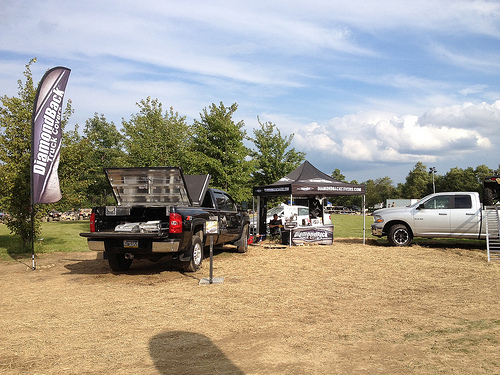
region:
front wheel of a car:
[393, 230, 403, 240]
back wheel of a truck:
[193, 239, 198, 254]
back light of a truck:
[168, 217, 182, 229]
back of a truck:
[131, 192, 160, 233]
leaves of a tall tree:
[214, 119, 231, 126]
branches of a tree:
[122, 117, 151, 138]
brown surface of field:
[316, 262, 344, 354]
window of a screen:
[430, 195, 465, 200]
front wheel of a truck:
[236, 232, 249, 244]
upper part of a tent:
[301, 177, 324, 184]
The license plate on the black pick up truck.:
[117, 239, 139, 251]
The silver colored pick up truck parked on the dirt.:
[365, 173, 499, 247]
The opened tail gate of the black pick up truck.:
[77, 227, 178, 241]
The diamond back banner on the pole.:
[32, 60, 74, 213]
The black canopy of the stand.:
[253, 152, 368, 198]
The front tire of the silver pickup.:
[386, 226, 410, 242]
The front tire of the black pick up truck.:
[239, 224, 254, 252]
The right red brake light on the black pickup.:
[165, 212, 182, 236]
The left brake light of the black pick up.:
[85, 209, 97, 231]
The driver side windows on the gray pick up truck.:
[415, 199, 472, 209]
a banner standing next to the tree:
[26, 66, 72, 263]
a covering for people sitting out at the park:
[256, 157, 366, 244]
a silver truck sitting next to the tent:
[372, 189, 497, 239]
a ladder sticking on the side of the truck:
[478, 202, 499, 271]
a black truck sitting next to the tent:
[88, 167, 252, 272]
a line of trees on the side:
[9, 93, 301, 225]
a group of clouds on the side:
[288, 104, 493, 170]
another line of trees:
[330, 168, 499, 201]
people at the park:
[50, 207, 95, 225]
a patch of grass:
[43, 215, 94, 249]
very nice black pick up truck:
[65, 136, 262, 293]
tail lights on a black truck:
[66, 205, 191, 266]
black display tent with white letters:
[250, 126, 380, 269]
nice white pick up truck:
[360, 167, 495, 287]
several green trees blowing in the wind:
[1, 92, 345, 265]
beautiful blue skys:
[67, 13, 454, 137]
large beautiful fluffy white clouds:
[260, 80, 465, 192]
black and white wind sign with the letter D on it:
[0, 51, 120, 276]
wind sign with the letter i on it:
[13, 56, 118, 244]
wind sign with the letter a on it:
[13, 39, 95, 254]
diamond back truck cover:
[24, 48, 71, 266]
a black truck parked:
[81, 144, 262, 346]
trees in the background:
[365, 168, 454, 227]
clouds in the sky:
[335, 86, 493, 205]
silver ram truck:
[371, 181, 456, 306]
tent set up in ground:
[227, 128, 419, 356]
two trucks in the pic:
[76, 120, 422, 339]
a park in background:
[252, 96, 462, 316]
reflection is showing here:
[83, 126, 190, 281]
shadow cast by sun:
[124, 321, 174, 359]